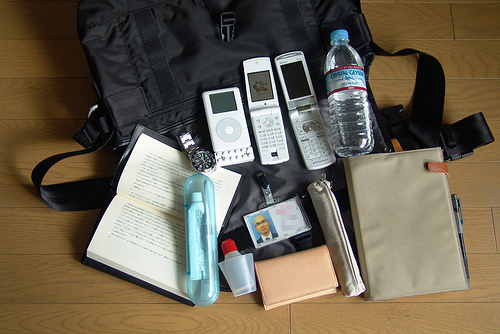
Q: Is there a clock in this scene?
A: No, there are no clocks.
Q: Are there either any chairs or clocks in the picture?
A: No, there are no clocks or chairs.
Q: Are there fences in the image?
A: No, there are no fences.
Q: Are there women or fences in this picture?
A: No, there are no fences or women.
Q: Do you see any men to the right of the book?
A: Yes, there is a man to the right of the book.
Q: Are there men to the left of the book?
A: No, the man is to the right of the book.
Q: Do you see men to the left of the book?
A: No, the man is to the right of the book.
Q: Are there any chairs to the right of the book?
A: No, there is a man to the right of the book.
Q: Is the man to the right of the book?
A: Yes, the man is to the right of the book.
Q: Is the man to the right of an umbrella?
A: No, the man is to the right of the book.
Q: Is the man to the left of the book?
A: No, the man is to the right of the book.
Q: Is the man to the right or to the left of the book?
A: The man is to the right of the book.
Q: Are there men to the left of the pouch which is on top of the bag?
A: Yes, there is a man to the left of the pouch.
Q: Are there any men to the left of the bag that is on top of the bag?
A: Yes, there is a man to the left of the pouch.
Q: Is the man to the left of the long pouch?
A: Yes, the man is to the left of the pouch.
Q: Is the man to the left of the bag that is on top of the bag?
A: Yes, the man is to the left of the pouch.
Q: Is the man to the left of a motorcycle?
A: No, the man is to the left of the pouch.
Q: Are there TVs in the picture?
A: No, there are no tvs.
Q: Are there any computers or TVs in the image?
A: No, there are no TVs or computers.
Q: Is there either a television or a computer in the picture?
A: No, there are no televisions or computers.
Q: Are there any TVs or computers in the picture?
A: No, there are no TVs or computers.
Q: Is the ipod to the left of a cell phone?
A: Yes, the ipod is to the left of a cell phone.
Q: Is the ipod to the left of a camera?
A: No, the ipod is to the left of a cell phone.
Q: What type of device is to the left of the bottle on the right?
A: The device is an ipod.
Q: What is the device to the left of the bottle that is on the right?
A: The device is an ipod.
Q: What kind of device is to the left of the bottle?
A: The device is an ipod.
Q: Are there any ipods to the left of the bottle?
A: Yes, there is an ipod to the left of the bottle.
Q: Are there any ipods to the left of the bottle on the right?
A: Yes, there is an ipod to the left of the bottle.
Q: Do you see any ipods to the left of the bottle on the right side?
A: Yes, there is an ipod to the left of the bottle.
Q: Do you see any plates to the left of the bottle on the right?
A: No, there is an ipod to the left of the bottle.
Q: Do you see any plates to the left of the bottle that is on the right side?
A: No, there is an ipod to the left of the bottle.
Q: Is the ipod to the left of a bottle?
A: Yes, the ipod is to the left of a bottle.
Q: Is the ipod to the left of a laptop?
A: No, the ipod is to the left of a bottle.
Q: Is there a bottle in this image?
A: Yes, there is a bottle.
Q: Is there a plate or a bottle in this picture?
A: Yes, there is a bottle.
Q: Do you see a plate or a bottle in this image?
A: Yes, there is a bottle.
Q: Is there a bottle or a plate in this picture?
A: Yes, there is a bottle.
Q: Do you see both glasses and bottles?
A: No, there is a bottle but no glasses.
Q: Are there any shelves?
A: No, there are no shelves.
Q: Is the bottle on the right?
A: Yes, the bottle is on the right of the image.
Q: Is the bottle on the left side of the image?
A: No, the bottle is on the right of the image.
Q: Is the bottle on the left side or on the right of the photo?
A: The bottle is on the right of the image.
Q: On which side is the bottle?
A: The bottle is on the right of the image.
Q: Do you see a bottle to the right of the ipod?
A: Yes, there is a bottle to the right of the ipod.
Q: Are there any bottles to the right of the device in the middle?
A: Yes, there is a bottle to the right of the ipod.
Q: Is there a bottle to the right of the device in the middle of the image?
A: Yes, there is a bottle to the right of the ipod.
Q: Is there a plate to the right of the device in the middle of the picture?
A: No, there is a bottle to the right of the ipod.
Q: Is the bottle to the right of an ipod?
A: Yes, the bottle is to the right of an ipod.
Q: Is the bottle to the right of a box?
A: No, the bottle is to the right of an ipod.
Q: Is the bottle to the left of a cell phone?
A: No, the bottle is to the right of a cell phone.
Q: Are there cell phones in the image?
A: Yes, there is a cell phone.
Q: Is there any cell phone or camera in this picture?
A: Yes, there is a cell phone.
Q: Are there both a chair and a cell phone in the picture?
A: No, there is a cell phone but no chairs.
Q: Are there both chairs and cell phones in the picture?
A: No, there is a cell phone but no chairs.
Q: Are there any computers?
A: No, there are no computers.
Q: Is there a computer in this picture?
A: No, there are no computers.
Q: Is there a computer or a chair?
A: No, there are no computers or chairs.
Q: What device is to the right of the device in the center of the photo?
A: The device is a cell phone.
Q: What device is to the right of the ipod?
A: The device is a cell phone.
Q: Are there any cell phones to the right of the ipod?
A: Yes, there is a cell phone to the right of the ipod.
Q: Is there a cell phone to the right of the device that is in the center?
A: Yes, there is a cell phone to the right of the ipod.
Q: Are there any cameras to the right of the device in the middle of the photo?
A: No, there is a cell phone to the right of the ipod.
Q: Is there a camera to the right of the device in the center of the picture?
A: No, there is a cell phone to the right of the ipod.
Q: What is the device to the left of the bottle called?
A: The device is a cell phone.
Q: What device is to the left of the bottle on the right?
A: The device is a cell phone.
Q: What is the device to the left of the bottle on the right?
A: The device is a cell phone.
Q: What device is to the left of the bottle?
A: The device is a cell phone.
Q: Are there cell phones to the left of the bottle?
A: Yes, there is a cell phone to the left of the bottle.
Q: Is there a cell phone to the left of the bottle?
A: Yes, there is a cell phone to the left of the bottle.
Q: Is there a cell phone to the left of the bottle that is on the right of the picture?
A: Yes, there is a cell phone to the left of the bottle.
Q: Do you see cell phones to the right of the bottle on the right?
A: No, the cell phone is to the left of the bottle.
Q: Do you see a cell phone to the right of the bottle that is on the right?
A: No, the cell phone is to the left of the bottle.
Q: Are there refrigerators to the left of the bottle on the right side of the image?
A: No, there is a cell phone to the left of the bottle.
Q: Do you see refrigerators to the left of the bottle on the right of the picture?
A: No, there is a cell phone to the left of the bottle.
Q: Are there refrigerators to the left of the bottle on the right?
A: No, there is a cell phone to the left of the bottle.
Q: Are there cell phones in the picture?
A: Yes, there is a cell phone.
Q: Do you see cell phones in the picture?
A: Yes, there is a cell phone.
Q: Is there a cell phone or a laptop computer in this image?
A: Yes, there is a cell phone.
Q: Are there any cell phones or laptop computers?
A: Yes, there is a cell phone.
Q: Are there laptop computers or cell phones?
A: Yes, there is a cell phone.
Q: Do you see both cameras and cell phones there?
A: No, there is a cell phone but no cameras.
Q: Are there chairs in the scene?
A: No, there are no chairs.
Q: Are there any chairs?
A: No, there are no chairs.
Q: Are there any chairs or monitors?
A: No, there are no chairs or monitors.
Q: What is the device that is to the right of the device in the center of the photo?
A: The device is a cell phone.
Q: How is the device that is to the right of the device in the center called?
A: The device is a cell phone.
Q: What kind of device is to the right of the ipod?
A: The device is a cell phone.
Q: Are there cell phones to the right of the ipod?
A: Yes, there is a cell phone to the right of the ipod.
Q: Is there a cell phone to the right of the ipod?
A: Yes, there is a cell phone to the right of the ipod.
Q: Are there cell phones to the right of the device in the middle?
A: Yes, there is a cell phone to the right of the ipod.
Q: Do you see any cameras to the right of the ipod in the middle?
A: No, there is a cell phone to the right of the ipod.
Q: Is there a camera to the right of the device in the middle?
A: No, there is a cell phone to the right of the ipod.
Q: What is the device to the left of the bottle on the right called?
A: The device is a cell phone.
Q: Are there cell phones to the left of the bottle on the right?
A: Yes, there is a cell phone to the left of the bottle.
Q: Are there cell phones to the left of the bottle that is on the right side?
A: Yes, there is a cell phone to the left of the bottle.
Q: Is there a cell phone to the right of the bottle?
A: No, the cell phone is to the left of the bottle.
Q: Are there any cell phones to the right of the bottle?
A: No, the cell phone is to the left of the bottle.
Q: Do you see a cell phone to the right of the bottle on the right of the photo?
A: No, the cell phone is to the left of the bottle.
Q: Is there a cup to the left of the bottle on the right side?
A: No, there is a cell phone to the left of the bottle.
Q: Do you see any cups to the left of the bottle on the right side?
A: No, there is a cell phone to the left of the bottle.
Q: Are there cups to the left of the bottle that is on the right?
A: No, there is a cell phone to the left of the bottle.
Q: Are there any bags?
A: Yes, there is a bag.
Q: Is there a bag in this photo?
A: Yes, there is a bag.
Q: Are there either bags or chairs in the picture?
A: Yes, there is a bag.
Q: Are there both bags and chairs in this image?
A: No, there is a bag but no chairs.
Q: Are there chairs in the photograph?
A: No, there are no chairs.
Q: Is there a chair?
A: No, there are no chairs.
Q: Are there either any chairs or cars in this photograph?
A: No, there are no chairs or cars.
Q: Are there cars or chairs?
A: No, there are no chairs or cars.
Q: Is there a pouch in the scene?
A: Yes, there is a pouch.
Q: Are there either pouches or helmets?
A: Yes, there is a pouch.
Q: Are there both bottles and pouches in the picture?
A: Yes, there are both a pouch and a bottle.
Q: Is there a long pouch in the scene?
A: Yes, there is a long pouch.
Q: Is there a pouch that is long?
A: Yes, there is a pouch that is long.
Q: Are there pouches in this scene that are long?
A: Yes, there is a pouch that is long.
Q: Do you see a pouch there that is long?
A: Yes, there is a pouch that is long.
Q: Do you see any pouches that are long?
A: Yes, there is a pouch that is long.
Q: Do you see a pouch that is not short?
A: Yes, there is a long pouch.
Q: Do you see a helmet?
A: No, there are no helmets.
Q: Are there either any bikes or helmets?
A: No, there are no helmets or bikes.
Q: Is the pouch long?
A: Yes, the pouch is long.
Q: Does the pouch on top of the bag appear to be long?
A: Yes, the pouch is long.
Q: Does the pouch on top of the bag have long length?
A: Yes, the pouch is long.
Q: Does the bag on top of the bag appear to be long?
A: Yes, the pouch is long.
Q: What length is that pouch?
A: The pouch is long.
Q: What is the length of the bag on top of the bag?
A: The pouch is long.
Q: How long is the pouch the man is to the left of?
A: The pouch is long.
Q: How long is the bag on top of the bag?
A: The pouch is long.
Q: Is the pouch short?
A: No, the pouch is long.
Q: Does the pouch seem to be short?
A: No, the pouch is long.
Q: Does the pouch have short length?
A: No, the pouch is long.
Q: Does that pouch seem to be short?
A: No, the pouch is long.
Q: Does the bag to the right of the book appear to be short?
A: No, the pouch is long.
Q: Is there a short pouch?
A: No, there is a pouch but it is long.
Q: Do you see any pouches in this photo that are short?
A: No, there is a pouch but it is long.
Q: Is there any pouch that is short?
A: No, there is a pouch but it is long.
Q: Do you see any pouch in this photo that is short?
A: No, there is a pouch but it is long.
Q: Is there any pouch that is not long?
A: No, there is a pouch but it is long.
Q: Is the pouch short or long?
A: The pouch is long.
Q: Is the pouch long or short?
A: The pouch is long.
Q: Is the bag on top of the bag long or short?
A: The pouch is long.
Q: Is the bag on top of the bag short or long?
A: The pouch is long.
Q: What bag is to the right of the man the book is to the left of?
A: The bag is a pouch.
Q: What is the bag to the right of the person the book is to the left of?
A: The bag is a pouch.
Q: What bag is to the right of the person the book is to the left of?
A: The bag is a pouch.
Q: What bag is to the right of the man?
A: The bag is a pouch.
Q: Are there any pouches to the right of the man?
A: Yes, there is a pouch to the right of the man.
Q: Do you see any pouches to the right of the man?
A: Yes, there is a pouch to the right of the man.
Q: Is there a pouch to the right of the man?
A: Yes, there is a pouch to the right of the man.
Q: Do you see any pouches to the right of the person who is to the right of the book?
A: Yes, there is a pouch to the right of the man.